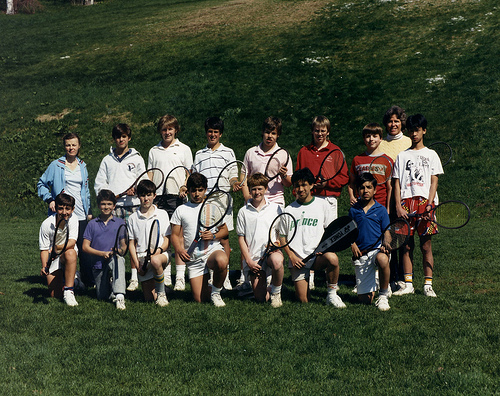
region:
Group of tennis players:
[34, 123, 474, 313]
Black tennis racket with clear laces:
[256, 208, 297, 275]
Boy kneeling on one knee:
[81, 190, 132, 315]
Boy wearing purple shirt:
[85, 193, 132, 309]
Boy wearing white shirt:
[229, 175, 291, 309]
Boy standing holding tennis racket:
[395, 119, 462, 313]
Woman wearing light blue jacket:
[28, 130, 94, 211]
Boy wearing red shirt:
[298, 120, 345, 194]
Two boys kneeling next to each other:
[240, 173, 350, 308]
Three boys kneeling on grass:
[34, 190, 180, 353]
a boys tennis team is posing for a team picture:
[6, 15, 496, 387]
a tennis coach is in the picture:
[38, 127, 99, 215]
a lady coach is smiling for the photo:
[380, 102, 408, 154]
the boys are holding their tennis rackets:
[41, 109, 470, 315]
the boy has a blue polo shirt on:
[350, 172, 389, 248]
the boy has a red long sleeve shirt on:
[295, 116, 347, 191]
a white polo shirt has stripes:
[192, 140, 238, 195]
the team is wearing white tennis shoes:
[48, 279, 438, 316]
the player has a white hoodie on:
[94, 123, 150, 195]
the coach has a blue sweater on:
[36, 134, 93, 216]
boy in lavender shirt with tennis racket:
[81, 190, 126, 309]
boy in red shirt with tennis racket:
[296, 114, 348, 228]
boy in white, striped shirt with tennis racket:
[191, 118, 245, 232]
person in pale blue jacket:
[36, 133, 93, 220]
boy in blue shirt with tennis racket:
[347, 173, 410, 311]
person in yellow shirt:
[372, 106, 412, 160]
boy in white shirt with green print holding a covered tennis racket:
[284, 167, 356, 310]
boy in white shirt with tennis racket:
[37, 192, 80, 307]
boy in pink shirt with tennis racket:
[239, 115, 295, 207]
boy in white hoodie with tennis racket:
[95, 121, 162, 208]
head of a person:
[40, 197, 87, 225]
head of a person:
[91, 180, 125, 220]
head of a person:
[129, 176, 174, 223]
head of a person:
[181, 169, 230, 210]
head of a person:
[237, 163, 272, 214]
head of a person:
[283, 157, 328, 216]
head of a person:
[347, 170, 383, 216]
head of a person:
[354, 122, 396, 169]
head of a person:
[304, 115, 347, 145]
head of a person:
[248, 103, 300, 145]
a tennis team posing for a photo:
[24, 104, 451, 305]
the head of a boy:
[103, 118, 141, 154]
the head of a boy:
[150, 105, 185, 148]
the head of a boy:
[200, 112, 232, 154]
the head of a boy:
[255, 112, 284, 152]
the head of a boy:
[302, 111, 339, 149]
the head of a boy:
[354, 117, 389, 156]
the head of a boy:
[401, 109, 434, 152]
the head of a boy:
[350, 170, 383, 205]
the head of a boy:
[284, 161, 319, 205]